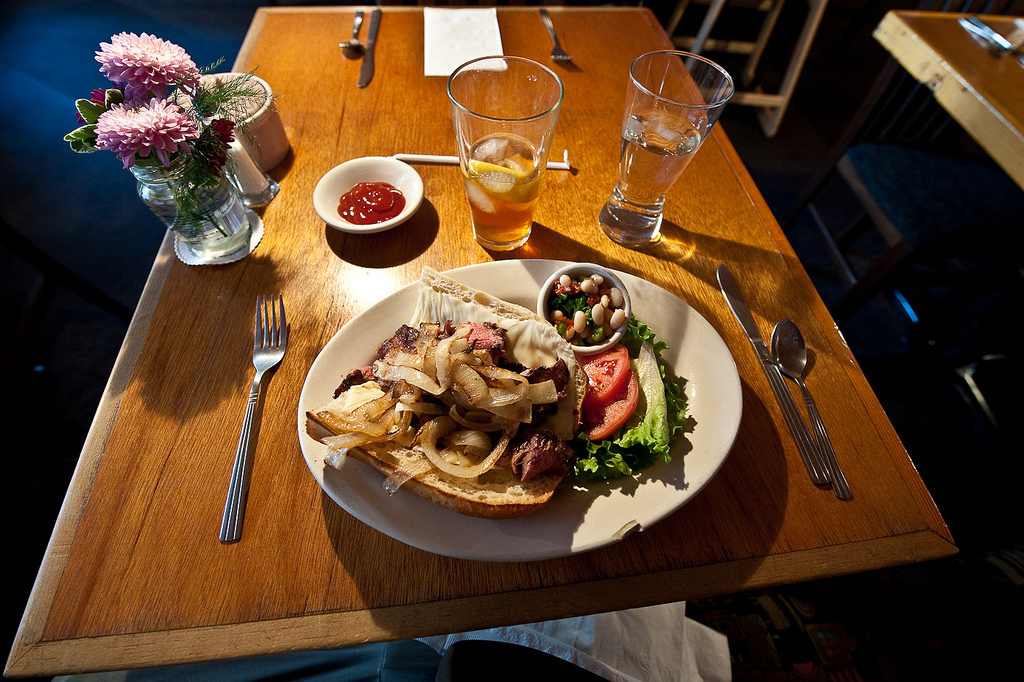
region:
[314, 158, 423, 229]
Ketchup in a small sauce dish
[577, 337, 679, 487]
Lettuce and tomato slices on the side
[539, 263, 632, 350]
Side of bean salad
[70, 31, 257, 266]
Jar of purple chrysanthemums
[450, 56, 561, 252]
Glass half full of beer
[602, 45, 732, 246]
Glass of water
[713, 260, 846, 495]
Silverware on the table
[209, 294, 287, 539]
Fork on the table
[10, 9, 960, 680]
Rectangular tan dinner table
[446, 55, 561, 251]
a glass of tea with ice cubes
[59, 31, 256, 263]
purple flowers in a glass vase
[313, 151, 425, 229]
red sauce inside a white small bowl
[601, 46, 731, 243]
a clean glass of water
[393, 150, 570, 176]
a white straw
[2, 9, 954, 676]
a long rectangular wooden table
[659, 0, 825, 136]
a stool made of wood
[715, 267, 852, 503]
a knife sitting next to a spoon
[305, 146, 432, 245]
white bowl of ketchup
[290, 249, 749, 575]
white plate of food on table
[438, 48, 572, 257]
clear glass of tea with lemon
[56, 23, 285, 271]
clear vase of lavender flowers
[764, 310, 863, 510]
silver spoon on tables edge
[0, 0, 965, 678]
wooden restaurant dining table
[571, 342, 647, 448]
sliced tomatoes on white plate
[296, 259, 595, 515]
meat and onion sandwich on hoagie roll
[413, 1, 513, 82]
white napkin on table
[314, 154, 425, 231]
the dish is small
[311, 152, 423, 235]
the dish is white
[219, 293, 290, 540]
the fork is made of metal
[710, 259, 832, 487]
the butterknife is silver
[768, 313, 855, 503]
the spoon is silver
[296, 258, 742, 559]
the plate is white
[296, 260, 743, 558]
the chipped area at the edge of the plate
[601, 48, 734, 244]
the cup is made of clear glass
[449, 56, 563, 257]
the lemon in the cup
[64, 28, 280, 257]
the flowers and leaves in the glass jar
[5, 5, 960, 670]
A wood dining table set for a meal.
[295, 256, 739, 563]
A large white plate with food on it.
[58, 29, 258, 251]
A small bouquet of flowers on the table.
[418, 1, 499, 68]
A folded white napkin on the end of the table.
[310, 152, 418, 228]
A small white bowl with something red in it.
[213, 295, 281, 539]
A fork on the table near the food.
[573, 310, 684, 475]
Sliced tomato and lettuce on the plate.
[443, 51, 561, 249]
A glass half full of tea and ice cubes.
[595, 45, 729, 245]
A glass of water with ice cubes.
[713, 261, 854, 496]
A knife and spoon beside the plate of food.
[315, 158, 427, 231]
a small white bowl of ketchup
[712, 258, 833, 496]
a gray butter knife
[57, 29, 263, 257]
a glass of pink flowers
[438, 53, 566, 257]
a tall glass of drink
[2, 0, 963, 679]
a large wooden table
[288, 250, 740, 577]
a large white plate of food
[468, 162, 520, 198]
a piece of ice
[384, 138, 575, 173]
a long white straw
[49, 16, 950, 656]
a wooden table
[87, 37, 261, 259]
purple flowers in a vase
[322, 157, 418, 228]
a small white bowl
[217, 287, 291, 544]
a fork on the table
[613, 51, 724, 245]
a glass on the table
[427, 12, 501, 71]
a napkin on the table